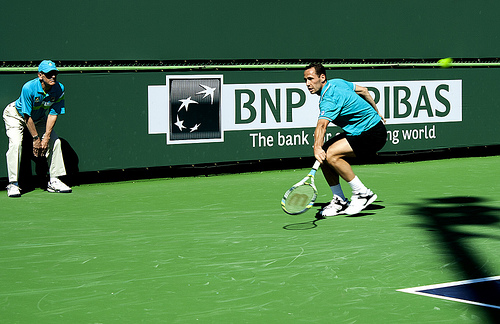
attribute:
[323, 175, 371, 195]
socks — white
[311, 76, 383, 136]
shirt — blue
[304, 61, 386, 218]
man — pictured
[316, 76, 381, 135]
shirt — blue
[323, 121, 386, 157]
shorts — black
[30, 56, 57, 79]
hat — blue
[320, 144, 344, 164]
knees — bent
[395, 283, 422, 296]
lines — white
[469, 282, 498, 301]
court — blue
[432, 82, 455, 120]
letter — green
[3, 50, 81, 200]
man — standing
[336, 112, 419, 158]
shorts — black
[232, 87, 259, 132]
letter — green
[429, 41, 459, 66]
ball — green, tennis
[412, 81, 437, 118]
letter — green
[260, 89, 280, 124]
letter — green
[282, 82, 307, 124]
letter — green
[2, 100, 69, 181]
pants — tan